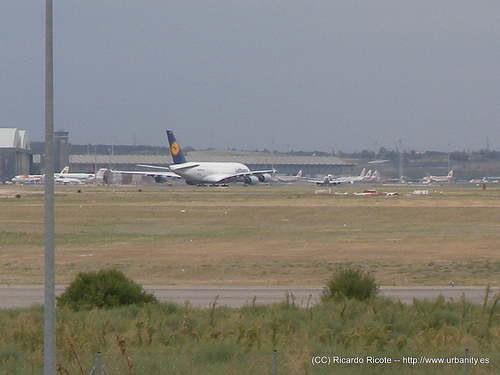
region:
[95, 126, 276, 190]
airplane with blue and yellow tail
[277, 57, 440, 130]
hazy sky in the distance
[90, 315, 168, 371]
brown weeds in between the green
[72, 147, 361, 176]
elongated airport terminal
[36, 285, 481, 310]
runway for planes to take off and land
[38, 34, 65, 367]
tall metal lamp post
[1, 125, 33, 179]
ovular airplane hangars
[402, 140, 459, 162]
houses in the distance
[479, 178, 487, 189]
red and white fire hydrant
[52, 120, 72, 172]
air traffic control tower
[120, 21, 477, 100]
overcast blue skies with no clouds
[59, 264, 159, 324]
overgrown green mound of shrubbery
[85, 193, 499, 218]
long tan dirt runway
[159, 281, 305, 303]
paved tan road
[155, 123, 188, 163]
airplane tail painted dark blue with yellow circular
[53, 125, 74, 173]
large airport tower with large window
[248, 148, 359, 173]
portion of large silver building with roof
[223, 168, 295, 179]
white airplane wing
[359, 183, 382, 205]
large spot painted red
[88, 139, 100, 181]
long silver pole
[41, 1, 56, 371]
gray pole next to the airport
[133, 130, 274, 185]
white jumbo jet plane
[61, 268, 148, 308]
bush next to the road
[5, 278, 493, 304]
road by the airport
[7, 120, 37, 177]
airplane hangar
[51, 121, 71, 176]
the airport flight control tower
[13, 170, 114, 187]
smaller passenger planes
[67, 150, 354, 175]
passenger waiting area and ticket area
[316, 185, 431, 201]
gear for the airplanes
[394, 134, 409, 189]
flight radio tower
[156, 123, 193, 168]
Navy blue and yellow airplane tail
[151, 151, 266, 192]
A white airplane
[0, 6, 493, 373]
A picture at an airport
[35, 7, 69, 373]
A silver pole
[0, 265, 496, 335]
Airplane landing strip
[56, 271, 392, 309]
Green bushes along the landing strip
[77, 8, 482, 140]
A dark grey sky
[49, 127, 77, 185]
Airport control tower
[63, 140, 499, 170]
A tree line along the back of the airport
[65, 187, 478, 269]
A field of brown grass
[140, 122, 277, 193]
Airplane sitting on field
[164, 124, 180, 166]
The wing of the airplane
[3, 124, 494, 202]
Here is the airport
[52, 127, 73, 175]
The control tower is here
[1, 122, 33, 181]
Hangers for the airplanes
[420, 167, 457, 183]
An airplane taking off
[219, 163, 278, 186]
The wing on the airplane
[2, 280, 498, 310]
A service road by the airport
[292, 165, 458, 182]
Planes waiting in the field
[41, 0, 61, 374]
A light pole by the road